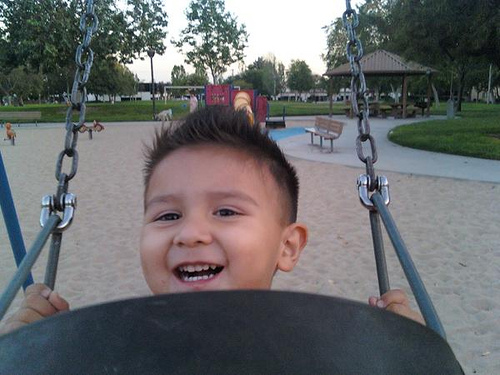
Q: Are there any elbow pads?
A: No, there are no elbow pads.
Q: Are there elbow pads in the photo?
A: No, there are no elbow pads.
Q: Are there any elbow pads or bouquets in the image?
A: No, there are no elbow pads or bouquets.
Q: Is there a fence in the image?
A: No, there are no fences.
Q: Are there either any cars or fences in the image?
A: No, there are no fences or cars.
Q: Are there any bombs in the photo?
A: No, there are no bombs.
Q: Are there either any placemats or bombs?
A: No, there are no bombs or placemats.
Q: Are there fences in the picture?
A: No, there are no fences.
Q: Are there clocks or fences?
A: No, there are no fences or clocks.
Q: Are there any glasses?
A: No, there are no glasses.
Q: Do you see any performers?
A: No, there are no performers.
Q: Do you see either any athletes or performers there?
A: No, there are no performers or athletes.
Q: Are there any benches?
A: Yes, there is a bench.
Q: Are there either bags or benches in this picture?
A: Yes, there is a bench.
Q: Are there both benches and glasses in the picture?
A: No, there is a bench but no glasses.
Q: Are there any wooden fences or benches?
A: Yes, there is a wood bench.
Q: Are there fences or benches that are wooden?
A: Yes, the bench is wooden.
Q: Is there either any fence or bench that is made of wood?
A: Yes, the bench is made of wood.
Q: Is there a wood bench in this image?
A: Yes, there is a wood bench.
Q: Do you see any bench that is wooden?
A: Yes, there is a bench that is wooden.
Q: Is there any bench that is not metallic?
A: Yes, there is a wooden bench.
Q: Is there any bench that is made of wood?
A: Yes, there is a bench that is made of wood.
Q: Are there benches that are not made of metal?
A: Yes, there is a bench that is made of wood.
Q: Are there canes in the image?
A: No, there are no canes.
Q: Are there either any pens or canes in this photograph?
A: No, there are no canes or pens.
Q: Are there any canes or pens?
A: No, there are no canes or pens.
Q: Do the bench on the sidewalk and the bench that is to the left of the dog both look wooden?
A: Yes, both the bench and the bench are wooden.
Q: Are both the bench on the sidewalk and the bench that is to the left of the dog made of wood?
A: Yes, both the bench and the bench are made of wood.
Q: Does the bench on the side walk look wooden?
A: Yes, the bench is wooden.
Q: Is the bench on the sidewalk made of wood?
A: Yes, the bench is made of wood.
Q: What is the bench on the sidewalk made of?
A: The bench is made of wood.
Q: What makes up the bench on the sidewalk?
A: The bench is made of wood.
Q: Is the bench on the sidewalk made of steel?
A: No, the bench is made of wood.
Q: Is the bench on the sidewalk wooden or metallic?
A: The bench is wooden.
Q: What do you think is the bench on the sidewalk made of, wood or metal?
A: The bench is made of wood.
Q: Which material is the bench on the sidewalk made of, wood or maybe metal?
A: The bench is made of wood.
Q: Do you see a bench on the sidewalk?
A: Yes, there is a bench on the sidewalk.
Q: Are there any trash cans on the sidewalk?
A: No, there is a bench on the sidewalk.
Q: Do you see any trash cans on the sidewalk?
A: No, there is a bench on the sidewalk.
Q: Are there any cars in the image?
A: No, there are no cars.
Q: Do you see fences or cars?
A: No, there are no cars or fences.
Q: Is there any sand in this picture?
A: Yes, there is sand.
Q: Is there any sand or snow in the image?
A: Yes, there is sand.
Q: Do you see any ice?
A: No, there is no ice.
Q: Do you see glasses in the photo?
A: No, there are no glasses.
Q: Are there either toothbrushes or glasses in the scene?
A: No, there are no glasses or toothbrushes.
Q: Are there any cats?
A: No, there are no cats.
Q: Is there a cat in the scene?
A: No, there are no cats.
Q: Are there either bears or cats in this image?
A: No, there are no cats or bears.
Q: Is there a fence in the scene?
A: No, there are no fences.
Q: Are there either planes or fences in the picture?
A: No, there are no fences or planes.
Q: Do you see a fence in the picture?
A: No, there are no fences.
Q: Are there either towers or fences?
A: No, there are no fences or towers.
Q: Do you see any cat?
A: No, there are no cats.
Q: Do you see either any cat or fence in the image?
A: No, there are no cats or fences.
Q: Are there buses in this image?
A: No, there are no buses.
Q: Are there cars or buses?
A: No, there are no buses or cars.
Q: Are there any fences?
A: No, there are no fences.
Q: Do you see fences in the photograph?
A: No, there are no fences.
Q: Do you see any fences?
A: No, there are no fences.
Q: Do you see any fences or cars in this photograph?
A: No, there are no fences or cars.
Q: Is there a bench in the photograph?
A: Yes, there is a bench.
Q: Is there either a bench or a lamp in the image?
A: Yes, there is a bench.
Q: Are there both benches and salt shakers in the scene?
A: No, there is a bench but no salt shakers.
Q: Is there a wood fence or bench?
A: Yes, there is a wood bench.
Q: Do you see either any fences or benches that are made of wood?
A: Yes, the bench is made of wood.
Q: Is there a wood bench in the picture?
A: Yes, there is a wood bench.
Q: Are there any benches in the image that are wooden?
A: Yes, there is a bench that is wooden.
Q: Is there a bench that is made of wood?
A: Yes, there is a bench that is made of wood.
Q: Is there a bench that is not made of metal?
A: Yes, there is a bench that is made of wood.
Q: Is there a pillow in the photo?
A: No, there are no pillows.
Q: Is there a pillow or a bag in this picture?
A: No, there are no pillows or bags.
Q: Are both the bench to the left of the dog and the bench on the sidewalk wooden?
A: Yes, both the bench and the bench are wooden.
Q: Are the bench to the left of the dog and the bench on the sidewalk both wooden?
A: Yes, both the bench and the bench are wooden.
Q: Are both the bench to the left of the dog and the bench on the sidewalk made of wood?
A: Yes, both the bench and the bench are made of wood.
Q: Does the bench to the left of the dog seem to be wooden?
A: Yes, the bench is wooden.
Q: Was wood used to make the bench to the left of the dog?
A: Yes, the bench is made of wood.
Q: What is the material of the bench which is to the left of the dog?
A: The bench is made of wood.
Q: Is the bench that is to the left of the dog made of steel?
A: No, the bench is made of wood.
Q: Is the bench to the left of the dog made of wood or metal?
A: The bench is made of wood.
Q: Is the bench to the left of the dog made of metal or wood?
A: The bench is made of wood.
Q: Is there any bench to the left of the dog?
A: Yes, there is a bench to the left of the dog.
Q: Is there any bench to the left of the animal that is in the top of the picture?
A: Yes, there is a bench to the left of the dog.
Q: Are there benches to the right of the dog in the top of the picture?
A: No, the bench is to the left of the dog.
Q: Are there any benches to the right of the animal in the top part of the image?
A: No, the bench is to the left of the dog.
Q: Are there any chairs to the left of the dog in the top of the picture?
A: No, there is a bench to the left of the dog.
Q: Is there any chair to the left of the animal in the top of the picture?
A: No, there is a bench to the left of the dog.